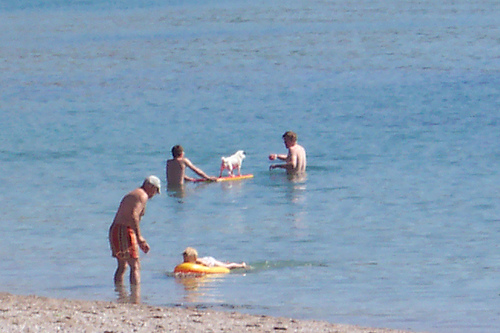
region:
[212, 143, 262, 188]
a dog on a paddle board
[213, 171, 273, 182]
a yellow paddle board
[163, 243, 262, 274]
a child floating on the water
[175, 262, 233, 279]
a yellow flotation device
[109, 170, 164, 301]
a man standing in the water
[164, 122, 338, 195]
two men watching the dog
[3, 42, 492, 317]
a large body of water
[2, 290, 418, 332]
a beach like shore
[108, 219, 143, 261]
a pair of swim trunks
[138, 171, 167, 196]
a baseball cap on one of the men's head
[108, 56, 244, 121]
this is the water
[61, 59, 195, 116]
the water is blue in color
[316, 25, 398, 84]
the water has ripples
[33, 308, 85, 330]
this is the ground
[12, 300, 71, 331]
the ground is sandy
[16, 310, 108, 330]
the sand is brown in color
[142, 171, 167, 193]
this is a cap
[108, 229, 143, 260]
this is a pair of shorts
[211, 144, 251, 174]
this is a dog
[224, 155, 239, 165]
the fur is white in color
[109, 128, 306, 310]
People swimming in ocean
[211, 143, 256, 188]
Dog standing on surf board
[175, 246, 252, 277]
Child on yellow floaty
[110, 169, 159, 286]
Man standing wearing swimsuit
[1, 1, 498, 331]
Water is blue and rippled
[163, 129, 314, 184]
People are waist deep in water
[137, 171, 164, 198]
Man is wearing hat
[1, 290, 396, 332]
Beach is tan and full of tracks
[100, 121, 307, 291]
Four people swimming in water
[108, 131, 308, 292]
Three people have backs turned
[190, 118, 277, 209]
the dog is riding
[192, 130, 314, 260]
the dog is riding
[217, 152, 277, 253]
the dog is riding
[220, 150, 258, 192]
the dog is riding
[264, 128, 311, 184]
A man in the water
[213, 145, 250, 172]
A dog in the water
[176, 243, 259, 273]
A person on a floating device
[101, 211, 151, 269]
A mans pair of swim trunks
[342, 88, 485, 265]
A body of calm water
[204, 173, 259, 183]
An orange boogie board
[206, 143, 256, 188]
A dog on a boogie board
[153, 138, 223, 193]
A person hold a boogie board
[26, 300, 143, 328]
A sandy beach by the water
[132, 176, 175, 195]
A hat on a man